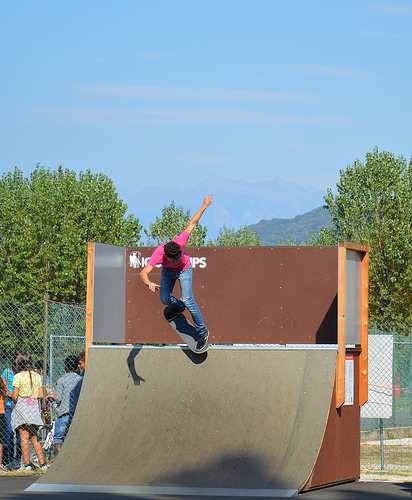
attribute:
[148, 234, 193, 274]
shirt — pink, short sleeved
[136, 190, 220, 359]
skateboarder — skateboarding, performing trick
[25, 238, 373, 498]
ramp — brown, paved, wooden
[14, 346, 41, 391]
ponytail — long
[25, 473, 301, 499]
line — white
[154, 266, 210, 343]
skater's jeans — blue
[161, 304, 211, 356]
skateboard — black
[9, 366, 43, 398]
shirt — yellow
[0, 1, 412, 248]
sky — clear, blue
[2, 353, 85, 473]
people — standing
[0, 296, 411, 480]
fence — gray, tall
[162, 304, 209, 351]
shoes — black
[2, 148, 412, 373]
trees — green